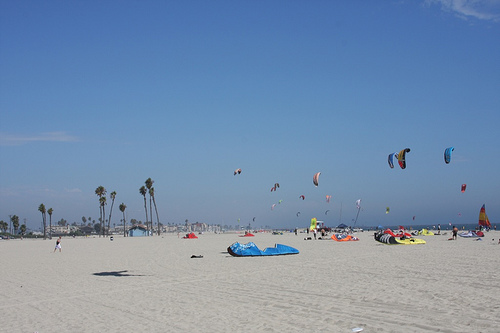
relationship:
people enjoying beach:
[41, 223, 496, 256] [1, 177, 496, 330]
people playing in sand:
[54, 236, 62, 253] [0, 228, 497, 330]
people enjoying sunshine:
[54, 236, 62, 253] [0, 0, 499, 332]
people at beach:
[54, 236, 62, 253] [0, 232, 499, 332]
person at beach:
[312, 229, 317, 239] [0, 232, 499, 332]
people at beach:
[452, 225, 459, 239] [0, 232, 499, 332]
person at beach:
[436, 223, 441, 233] [0, 232, 499, 332]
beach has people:
[0, 229, 500, 333] [452, 225, 459, 239]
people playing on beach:
[248, 207, 469, 243] [86, 234, 370, 329]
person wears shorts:
[318, 226, 326, 238] [451, 231, 458, 239]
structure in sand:
[330, 232, 356, 243] [0, 241, 500, 331]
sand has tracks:
[0, 228, 497, 330] [216, 278, 466, 322]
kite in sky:
[460, 181, 467, 192] [0, 1, 498, 231]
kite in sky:
[385, 150, 400, 168] [0, 1, 498, 231]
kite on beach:
[181, 229, 203, 239] [260, 263, 440, 313]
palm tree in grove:
[147, 182, 168, 228] [4, 179, 163, 235]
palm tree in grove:
[139, 184, 149, 227] [4, 179, 163, 235]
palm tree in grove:
[119, 202, 131, 237] [4, 179, 163, 235]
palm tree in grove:
[95, 186, 106, 227] [4, 179, 163, 235]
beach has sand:
[1, 207, 476, 321] [37, 264, 195, 328]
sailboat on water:
[469, 190, 484, 230] [418, 212, 472, 238]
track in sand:
[325, 305, 377, 322] [18, 278, 244, 322]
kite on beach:
[220, 237, 320, 264] [0, 229, 500, 333]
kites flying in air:
[229, 142, 498, 228] [0, 21, 495, 198]